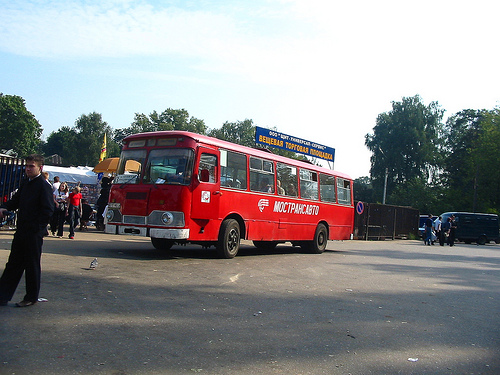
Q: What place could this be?
A: It is a pavement.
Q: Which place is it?
A: It is a pavement.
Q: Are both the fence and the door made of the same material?
A: Yes, both the fence and the door are made of metal.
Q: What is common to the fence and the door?
A: The material, both the fence and the door are metallic.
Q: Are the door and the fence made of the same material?
A: Yes, both the door and the fence are made of metal.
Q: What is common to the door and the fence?
A: The material, both the door and the fence are metallic.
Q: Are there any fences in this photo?
A: Yes, there is a fence.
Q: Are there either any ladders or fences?
A: Yes, there is a fence.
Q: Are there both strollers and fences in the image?
A: No, there is a fence but no strollers.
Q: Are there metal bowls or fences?
A: Yes, there is a metal fence.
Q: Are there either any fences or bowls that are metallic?
A: Yes, the fence is metallic.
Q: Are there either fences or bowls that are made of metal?
A: Yes, the fence is made of metal.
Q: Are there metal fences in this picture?
A: Yes, there is a metal fence.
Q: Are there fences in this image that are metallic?
A: Yes, there is a fence that is metallic.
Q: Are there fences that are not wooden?
A: Yes, there is a metallic fence.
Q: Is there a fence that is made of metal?
A: Yes, there is a fence that is made of metal.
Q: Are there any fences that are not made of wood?
A: Yes, there is a fence that is made of metal.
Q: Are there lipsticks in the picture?
A: No, there are no lipsticks.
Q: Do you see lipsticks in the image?
A: No, there are no lipsticks.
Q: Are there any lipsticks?
A: No, there are no lipsticks.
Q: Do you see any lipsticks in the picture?
A: No, there are no lipsticks.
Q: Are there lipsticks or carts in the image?
A: No, there are no lipsticks or carts.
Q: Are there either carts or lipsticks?
A: No, there are no lipsticks or carts.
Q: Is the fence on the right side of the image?
A: Yes, the fence is on the right of the image.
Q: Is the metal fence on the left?
A: No, the fence is on the right of the image.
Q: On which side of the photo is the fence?
A: The fence is on the right of the image.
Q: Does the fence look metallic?
A: Yes, the fence is metallic.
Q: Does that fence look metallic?
A: Yes, the fence is metallic.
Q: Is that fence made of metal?
A: Yes, the fence is made of metal.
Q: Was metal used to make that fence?
A: Yes, the fence is made of metal.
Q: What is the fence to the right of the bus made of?
A: The fence is made of metal.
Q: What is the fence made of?
A: The fence is made of metal.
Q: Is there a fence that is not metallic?
A: No, there is a fence but it is metallic.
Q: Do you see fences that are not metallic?
A: No, there is a fence but it is metallic.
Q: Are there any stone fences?
A: No, there is a fence but it is made of metal.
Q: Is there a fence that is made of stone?
A: No, there is a fence but it is made of metal.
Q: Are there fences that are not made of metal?
A: No, there is a fence but it is made of metal.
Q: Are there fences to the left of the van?
A: Yes, there is a fence to the left of the van.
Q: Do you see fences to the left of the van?
A: Yes, there is a fence to the left of the van.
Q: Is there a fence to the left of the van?
A: Yes, there is a fence to the left of the van.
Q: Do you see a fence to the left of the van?
A: Yes, there is a fence to the left of the van.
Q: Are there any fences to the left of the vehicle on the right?
A: Yes, there is a fence to the left of the van.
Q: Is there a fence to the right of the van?
A: No, the fence is to the left of the van.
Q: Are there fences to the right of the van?
A: No, the fence is to the left of the van.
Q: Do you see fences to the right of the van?
A: No, the fence is to the left of the van.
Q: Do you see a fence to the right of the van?
A: No, the fence is to the left of the van.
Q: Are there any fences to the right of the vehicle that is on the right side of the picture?
A: No, the fence is to the left of the van.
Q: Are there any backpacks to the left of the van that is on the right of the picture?
A: No, there is a fence to the left of the van.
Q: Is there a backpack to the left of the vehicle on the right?
A: No, there is a fence to the left of the van.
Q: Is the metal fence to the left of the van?
A: Yes, the fence is to the left of the van.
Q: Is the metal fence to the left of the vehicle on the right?
A: Yes, the fence is to the left of the van.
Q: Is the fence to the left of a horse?
A: No, the fence is to the left of the van.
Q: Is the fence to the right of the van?
A: No, the fence is to the left of the van.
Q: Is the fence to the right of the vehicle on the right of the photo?
A: No, the fence is to the left of the van.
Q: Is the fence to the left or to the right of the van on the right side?
A: The fence is to the left of the van.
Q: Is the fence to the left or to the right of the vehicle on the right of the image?
A: The fence is to the left of the van.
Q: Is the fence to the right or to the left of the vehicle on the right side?
A: The fence is to the left of the van.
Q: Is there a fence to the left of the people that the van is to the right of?
A: Yes, there is a fence to the left of the people.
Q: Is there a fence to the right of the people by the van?
A: No, the fence is to the left of the people.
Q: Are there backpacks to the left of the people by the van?
A: No, there is a fence to the left of the people.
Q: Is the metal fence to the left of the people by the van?
A: Yes, the fence is to the left of the people.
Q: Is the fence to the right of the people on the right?
A: No, the fence is to the left of the people.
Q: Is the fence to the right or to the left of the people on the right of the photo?
A: The fence is to the left of the people.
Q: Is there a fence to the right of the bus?
A: Yes, there is a fence to the right of the bus.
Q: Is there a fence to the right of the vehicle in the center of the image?
A: Yes, there is a fence to the right of the bus.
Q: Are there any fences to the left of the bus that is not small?
A: No, the fence is to the right of the bus.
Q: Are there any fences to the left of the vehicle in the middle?
A: No, the fence is to the right of the bus.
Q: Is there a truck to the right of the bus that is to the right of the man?
A: No, there is a fence to the right of the bus.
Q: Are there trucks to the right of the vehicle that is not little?
A: No, there is a fence to the right of the bus.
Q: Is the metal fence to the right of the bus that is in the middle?
A: Yes, the fence is to the right of the bus.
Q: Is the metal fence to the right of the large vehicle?
A: Yes, the fence is to the right of the bus.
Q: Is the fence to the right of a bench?
A: No, the fence is to the right of the bus.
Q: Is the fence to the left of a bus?
A: No, the fence is to the right of a bus.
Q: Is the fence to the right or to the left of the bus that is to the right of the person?
A: The fence is to the right of the bus.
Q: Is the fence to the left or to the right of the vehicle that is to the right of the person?
A: The fence is to the right of the bus.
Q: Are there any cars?
A: No, there are no cars.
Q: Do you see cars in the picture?
A: No, there are no cars.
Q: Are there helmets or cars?
A: No, there are no cars or helmets.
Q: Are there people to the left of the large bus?
A: Yes, there is a person to the left of the bus.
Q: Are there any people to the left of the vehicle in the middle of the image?
A: Yes, there is a person to the left of the bus.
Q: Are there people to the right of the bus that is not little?
A: No, the person is to the left of the bus.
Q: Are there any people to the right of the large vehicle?
A: No, the person is to the left of the bus.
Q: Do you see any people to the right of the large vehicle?
A: No, the person is to the left of the bus.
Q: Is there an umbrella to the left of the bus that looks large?
A: No, there is a person to the left of the bus.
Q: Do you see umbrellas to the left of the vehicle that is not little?
A: No, there is a person to the left of the bus.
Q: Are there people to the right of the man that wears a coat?
A: Yes, there is a person to the right of the man.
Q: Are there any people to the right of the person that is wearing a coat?
A: Yes, there is a person to the right of the man.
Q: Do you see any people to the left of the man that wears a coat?
A: No, the person is to the right of the man.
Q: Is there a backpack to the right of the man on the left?
A: No, there is a person to the right of the man.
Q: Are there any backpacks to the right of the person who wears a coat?
A: No, there is a person to the right of the man.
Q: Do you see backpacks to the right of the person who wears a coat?
A: No, there is a person to the right of the man.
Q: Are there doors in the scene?
A: Yes, there is a door.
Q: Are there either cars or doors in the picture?
A: Yes, there is a door.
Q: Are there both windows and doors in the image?
A: Yes, there are both a door and windows.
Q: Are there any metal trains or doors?
A: Yes, there is a metal door.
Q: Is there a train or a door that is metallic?
A: Yes, the door is metallic.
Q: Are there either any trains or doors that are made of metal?
A: Yes, the door is made of metal.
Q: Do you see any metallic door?
A: Yes, there is a metal door.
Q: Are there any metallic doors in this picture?
A: Yes, there is a metal door.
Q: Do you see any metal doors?
A: Yes, there is a metal door.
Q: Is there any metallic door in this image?
A: Yes, there is a metal door.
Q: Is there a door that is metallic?
A: Yes, there is a door that is metallic.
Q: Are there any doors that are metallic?
A: Yes, there is a door that is metallic.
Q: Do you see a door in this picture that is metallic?
A: Yes, there is a door that is metallic.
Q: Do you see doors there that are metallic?
A: Yes, there is a door that is metallic.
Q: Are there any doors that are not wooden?
A: Yes, there is a metallic door.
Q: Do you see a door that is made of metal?
A: Yes, there is a door that is made of metal.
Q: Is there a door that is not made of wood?
A: Yes, there is a door that is made of metal.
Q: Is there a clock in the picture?
A: No, there are no clocks.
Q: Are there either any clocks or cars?
A: No, there are no clocks or cars.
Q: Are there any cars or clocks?
A: No, there are no clocks or cars.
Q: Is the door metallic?
A: Yes, the door is metallic.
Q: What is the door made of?
A: The door is made of metal.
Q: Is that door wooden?
A: No, the door is metallic.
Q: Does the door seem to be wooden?
A: No, the door is metallic.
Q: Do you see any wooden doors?
A: No, there is a door but it is metallic.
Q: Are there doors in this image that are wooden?
A: No, there is a door but it is metallic.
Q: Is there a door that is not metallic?
A: No, there is a door but it is metallic.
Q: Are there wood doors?
A: No, there is a door but it is made of metal.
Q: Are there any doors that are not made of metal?
A: No, there is a door but it is made of metal.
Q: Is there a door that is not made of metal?
A: No, there is a door but it is made of metal.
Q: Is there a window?
A: Yes, there is a window.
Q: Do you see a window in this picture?
A: Yes, there is a window.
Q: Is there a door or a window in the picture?
A: Yes, there is a window.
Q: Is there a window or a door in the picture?
A: Yes, there is a window.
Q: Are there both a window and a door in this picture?
A: Yes, there are both a window and a door.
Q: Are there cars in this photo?
A: No, there are no cars.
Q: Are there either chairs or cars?
A: No, there are no cars or chairs.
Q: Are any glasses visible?
A: No, there are no glasses.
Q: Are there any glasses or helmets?
A: No, there are no glasses or helmets.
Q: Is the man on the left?
A: Yes, the man is on the left of the image.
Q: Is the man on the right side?
A: No, the man is on the left of the image.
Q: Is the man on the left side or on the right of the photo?
A: The man is on the left of the image.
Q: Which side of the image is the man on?
A: The man is on the left of the image.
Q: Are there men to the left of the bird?
A: Yes, there is a man to the left of the bird.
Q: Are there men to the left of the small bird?
A: Yes, there is a man to the left of the bird.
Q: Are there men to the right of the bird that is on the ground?
A: No, the man is to the left of the bird.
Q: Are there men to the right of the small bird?
A: No, the man is to the left of the bird.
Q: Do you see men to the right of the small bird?
A: No, the man is to the left of the bird.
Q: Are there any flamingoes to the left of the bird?
A: No, there is a man to the left of the bird.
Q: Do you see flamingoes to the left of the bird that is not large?
A: No, there is a man to the left of the bird.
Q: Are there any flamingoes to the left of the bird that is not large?
A: No, there is a man to the left of the bird.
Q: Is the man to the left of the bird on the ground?
A: Yes, the man is to the left of the bird.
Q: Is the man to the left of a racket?
A: No, the man is to the left of the bird.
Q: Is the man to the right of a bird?
A: No, the man is to the left of a bird.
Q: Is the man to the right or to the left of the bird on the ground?
A: The man is to the left of the bird.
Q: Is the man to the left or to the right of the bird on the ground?
A: The man is to the left of the bird.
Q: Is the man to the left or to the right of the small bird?
A: The man is to the left of the bird.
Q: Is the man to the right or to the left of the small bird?
A: The man is to the left of the bird.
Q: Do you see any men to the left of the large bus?
A: Yes, there is a man to the left of the bus.